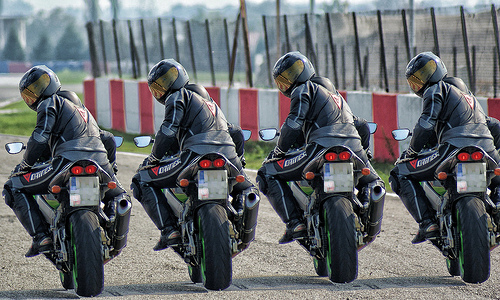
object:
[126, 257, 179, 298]
gravel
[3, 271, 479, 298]
shadows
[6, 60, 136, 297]
motorcycle rider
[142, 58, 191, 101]
helmet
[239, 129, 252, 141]
mirror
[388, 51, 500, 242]
man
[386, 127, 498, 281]
motorcycle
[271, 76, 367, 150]
jacket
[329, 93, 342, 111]
logo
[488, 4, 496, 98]
poles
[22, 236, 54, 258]
shoe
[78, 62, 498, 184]
tarp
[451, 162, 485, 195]
plate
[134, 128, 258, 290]
bike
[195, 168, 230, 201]
place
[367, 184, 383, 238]
pipe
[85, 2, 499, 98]
fence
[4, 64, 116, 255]
man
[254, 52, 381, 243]
man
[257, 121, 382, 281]
motorcycle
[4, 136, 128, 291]
motorcycle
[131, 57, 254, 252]
man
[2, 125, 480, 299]
motorcycles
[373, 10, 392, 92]
pole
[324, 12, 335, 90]
pole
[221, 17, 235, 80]
pole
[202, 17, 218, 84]
pole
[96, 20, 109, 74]
pole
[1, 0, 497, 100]
background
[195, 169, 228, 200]
license plate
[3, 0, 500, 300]
photo